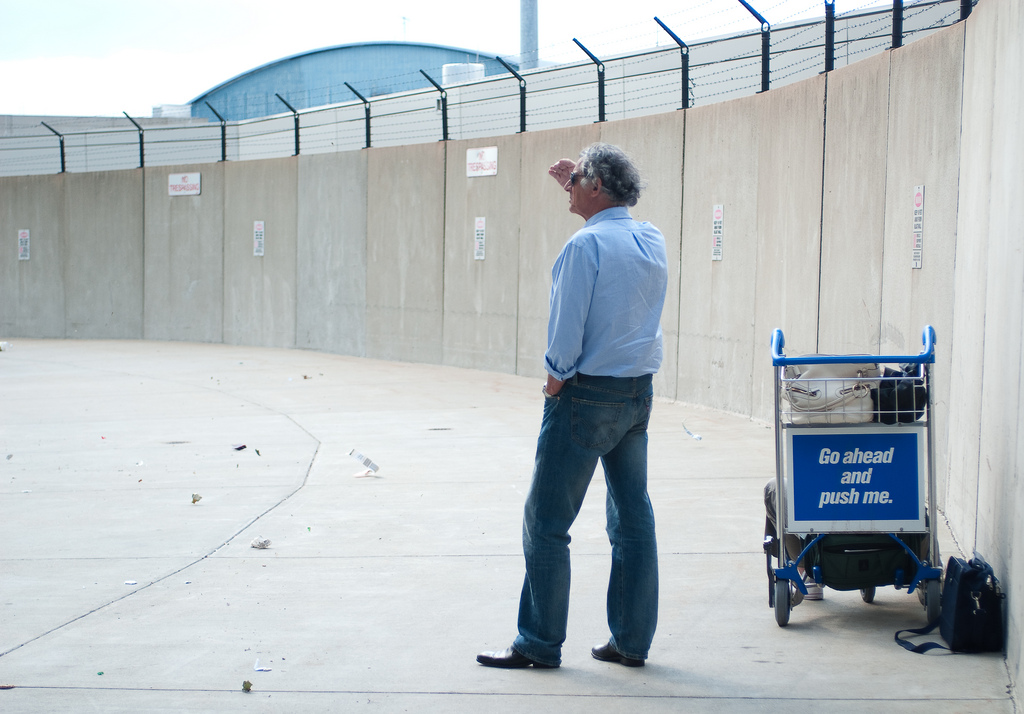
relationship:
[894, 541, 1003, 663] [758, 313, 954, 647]
bag near luggage cart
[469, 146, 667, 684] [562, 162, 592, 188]
man with sunglasses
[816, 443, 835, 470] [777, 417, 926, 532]
letter on sign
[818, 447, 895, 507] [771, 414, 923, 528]
letter on sign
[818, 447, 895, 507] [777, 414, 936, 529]
letter on sign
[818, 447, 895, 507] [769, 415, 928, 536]
letter on sign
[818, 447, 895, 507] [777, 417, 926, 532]
letter on sign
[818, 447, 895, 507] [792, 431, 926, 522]
letter on sign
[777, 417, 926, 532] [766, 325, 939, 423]
sign attached to cart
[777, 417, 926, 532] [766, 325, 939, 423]
sign mounted on cart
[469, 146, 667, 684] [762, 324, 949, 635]
man standing next to luggage cart